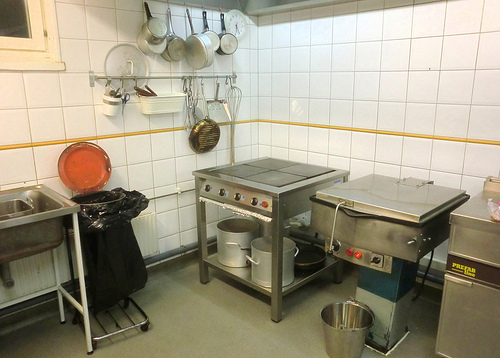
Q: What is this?
A: Kitchen.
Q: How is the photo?
A: Clear.